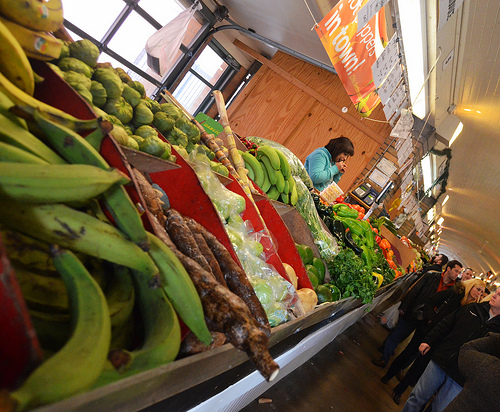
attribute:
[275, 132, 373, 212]
woman — standing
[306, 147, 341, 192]
top — blue